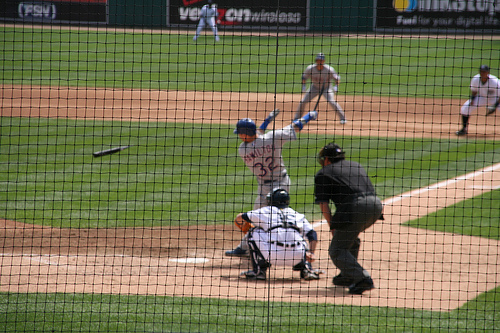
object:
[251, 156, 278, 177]
number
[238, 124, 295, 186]
jersey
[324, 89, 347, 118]
leg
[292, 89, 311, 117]
leg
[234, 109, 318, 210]
batter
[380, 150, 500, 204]
line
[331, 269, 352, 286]
shoe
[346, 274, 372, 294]
shoe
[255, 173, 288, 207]
grey pants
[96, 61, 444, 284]
wrong picture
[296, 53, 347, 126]
person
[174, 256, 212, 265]
homeplate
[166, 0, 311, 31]
banner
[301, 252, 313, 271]
leg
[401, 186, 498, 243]
grass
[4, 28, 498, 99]
grass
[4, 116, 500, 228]
grass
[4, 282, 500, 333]
grass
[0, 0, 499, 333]
baseball field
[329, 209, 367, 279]
leg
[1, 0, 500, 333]
fence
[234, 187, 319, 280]
catcher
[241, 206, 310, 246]
shirt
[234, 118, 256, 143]
head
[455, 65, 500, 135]
person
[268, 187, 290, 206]
head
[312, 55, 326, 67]
head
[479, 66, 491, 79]
head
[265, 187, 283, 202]
mask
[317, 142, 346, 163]
head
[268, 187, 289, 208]
helmet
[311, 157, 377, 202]
black shirt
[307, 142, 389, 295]
person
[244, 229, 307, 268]
white pants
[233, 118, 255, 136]
hat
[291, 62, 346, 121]
uniform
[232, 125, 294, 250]
uniform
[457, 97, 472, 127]
leg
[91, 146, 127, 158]
bat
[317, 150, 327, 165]
mask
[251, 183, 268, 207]
leg